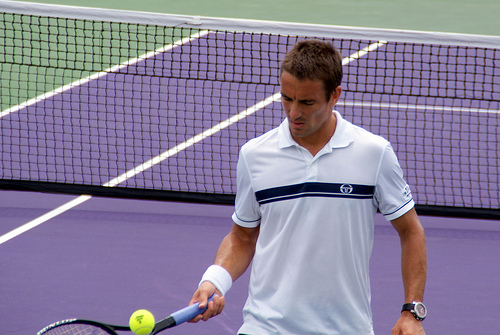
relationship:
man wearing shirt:
[182, 28, 448, 334] [225, 135, 405, 318]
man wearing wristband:
[182, 28, 448, 334] [200, 262, 233, 291]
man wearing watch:
[182, 28, 448, 334] [402, 299, 429, 320]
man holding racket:
[182, 28, 448, 334] [32, 292, 203, 334]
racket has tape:
[32, 292, 203, 334] [174, 299, 214, 325]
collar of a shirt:
[333, 121, 360, 157] [225, 135, 405, 318]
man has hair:
[182, 28, 448, 334] [283, 41, 340, 94]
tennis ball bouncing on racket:
[126, 309, 157, 333] [32, 292, 203, 334]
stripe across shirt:
[255, 179, 374, 204] [225, 135, 405, 318]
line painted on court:
[13, 207, 57, 234] [48, 222, 153, 295]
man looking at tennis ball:
[182, 28, 448, 334] [126, 309, 157, 333]